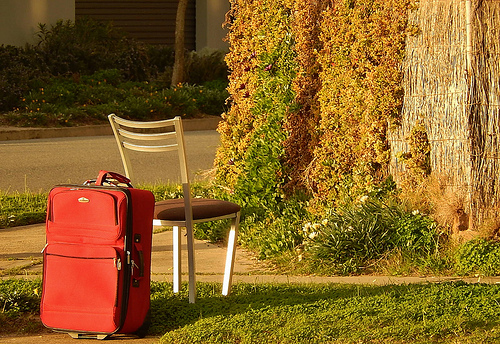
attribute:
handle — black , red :
[132, 237, 144, 287]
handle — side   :
[127, 240, 150, 282]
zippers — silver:
[106, 192, 157, 337]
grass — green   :
[8, 273, 499, 340]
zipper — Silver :
[121, 237, 133, 284]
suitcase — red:
[46, 185, 141, 335]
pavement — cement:
[43, 147, 75, 172]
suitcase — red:
[37, 168, 154, 341]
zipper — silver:
[113, 240, 134, 264]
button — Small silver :
[131, 272, 139, 290]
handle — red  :
[135, 221, 144, 284]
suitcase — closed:
[27, 169, 185, 333]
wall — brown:
[3, 4, 66, 37]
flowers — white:
[295, 216, 330, 262]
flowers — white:
[285, 192, 347, 261]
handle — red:
[131, 228, 147, 288]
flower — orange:
[149, 108, 153, 115]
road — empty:
[1, 125, 220, 190]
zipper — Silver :
[113, 256, 124, 270]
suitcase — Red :
[21, 163, 178, 340]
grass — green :
[281, 277, 434, 327]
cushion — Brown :
[152, 195, 238, 222]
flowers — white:
[296, 177, 432, 267]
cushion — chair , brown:
[153, 194, 244, 221]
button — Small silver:
[132, 234, 140, 242]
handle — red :
[134, 245, 143, 280]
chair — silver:
[105, 105, 245, 295]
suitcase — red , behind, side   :
[33, 173, 159, 333]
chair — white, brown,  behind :
[112, 112, 244, 309]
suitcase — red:
[34, 166, 164, 339]